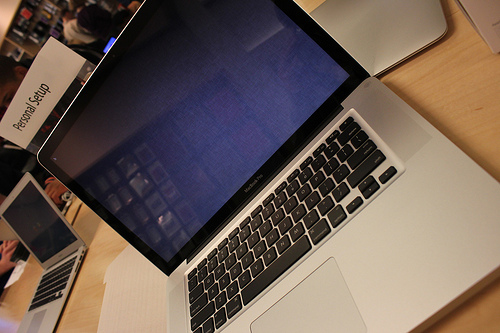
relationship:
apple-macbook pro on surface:
[37, 0, 499, 332] [4, 0, 496, 330]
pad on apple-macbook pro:
[255, 249, 365, 331] [37, 0, 499, 332]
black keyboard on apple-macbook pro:
[187, 116, 398, 332] [37, 0, 499, 332]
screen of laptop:
[62, 64, 302, 214] [81, 63, 473, 291]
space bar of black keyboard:
[238, 235, 315, 300] [187, 116, 398, 332]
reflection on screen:
[52, 5, 220, 262] [35, 0, 370, 277]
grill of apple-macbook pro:
[348, 87, 441, 172] [37, 0, 499, 332]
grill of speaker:
[348, 87, 441, 172] [347, 90, 434, 164]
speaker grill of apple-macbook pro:
[166, 279, 189, 331] [37, 0, 499, 332]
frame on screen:
[32, 1, 370, 273] [10, 3, 366, 270]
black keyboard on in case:
[187, 116, 398, 332] [170, 77, 493, 323]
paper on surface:
[96, 253, 192, 332] [4, 0, 496, 330]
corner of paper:
[99, 260, 122, 284] [96, 253, 192, 332]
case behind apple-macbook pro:
[309, 0, 449, 78] [37, 0, 499, 332]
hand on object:
[0, 240, 15, 277] [9, 241, 29, 261]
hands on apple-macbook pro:
[1, 175, 71, 275] [37, 0, 499, 332]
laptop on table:
[5, 162, 89, 331] [4, 1, 498, 331]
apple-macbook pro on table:
[37, 0, 499, 332] [4, 1, 498, 331]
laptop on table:
[0, 171, 88, 332] [4, 1, 498, 331]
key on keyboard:
[180, 300, 220, 326] [176, 104, 391, 329]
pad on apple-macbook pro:
[249, 257, 366, 333] [37, 0, 499, 332]